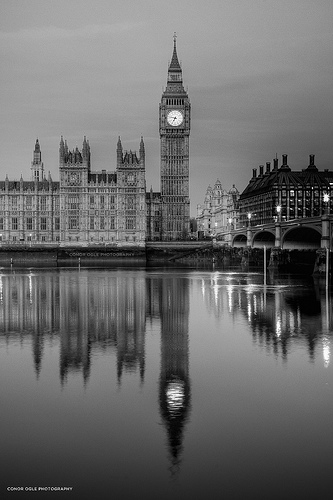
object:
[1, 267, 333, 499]
water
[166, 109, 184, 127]
clock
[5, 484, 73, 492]
label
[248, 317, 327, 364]
ripples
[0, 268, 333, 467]
reflection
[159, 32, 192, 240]
clocktower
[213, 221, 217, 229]
lights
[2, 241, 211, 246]
street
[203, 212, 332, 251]
bridge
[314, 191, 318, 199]
windows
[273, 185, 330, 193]
rows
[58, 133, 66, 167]
towers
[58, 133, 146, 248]
buildings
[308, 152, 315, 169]
chimney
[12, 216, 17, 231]
windows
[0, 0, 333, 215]
sky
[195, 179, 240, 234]
building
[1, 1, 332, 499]
london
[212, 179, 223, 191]
domes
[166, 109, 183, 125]
face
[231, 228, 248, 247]
arches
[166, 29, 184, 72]
spire